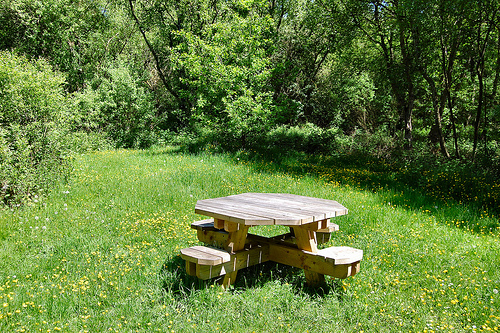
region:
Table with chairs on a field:
[164, 174, 374, 301]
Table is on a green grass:
[19, 124, 497, 331]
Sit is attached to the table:
[297, 237, 376, 291]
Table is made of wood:
[189, 176, 353, 231]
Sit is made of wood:
[174, 239, 237, 290]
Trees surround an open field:
[5, 2, 484, 159]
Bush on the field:
[5, 42, 88, 211]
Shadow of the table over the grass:
[240, 259, 296, 305]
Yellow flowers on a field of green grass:
[8, 254, 116, 314]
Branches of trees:
[356, 19, 493, 136]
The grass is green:
[20, 4, 490, 330]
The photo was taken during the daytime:
[53, 15, 492, 330]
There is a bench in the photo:
[20, 8, 437, 320]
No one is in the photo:
[24, 19, 440, 329]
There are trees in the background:
[25, 17, 483, 289]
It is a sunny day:
[40, 17, 470, 322]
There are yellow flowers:
[23, 41, 455, 329]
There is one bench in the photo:
[21, 6, 478, 326]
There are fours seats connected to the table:
[18, 24, 469, 331]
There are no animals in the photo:
[11, 19, 498, 329]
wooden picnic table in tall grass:
[177, 186, 363, 288]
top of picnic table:
[189, 189, 352, 224]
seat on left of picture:
[310, 243, 366, 277]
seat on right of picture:
[173, 243, 237, 281]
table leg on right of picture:
[286, 227, 326, 293]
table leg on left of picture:
[226, 223, 249, 293]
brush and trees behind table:
[8, 4, 493, 148]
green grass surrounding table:
[24, 153, 488, 329]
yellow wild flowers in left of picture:
[3, 198, 178, 323]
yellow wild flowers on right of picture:
[371, 169, 498, 323]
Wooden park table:
[161, 156, 373, 297]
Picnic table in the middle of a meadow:
[168, 176, 371, 306]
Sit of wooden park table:
[297, 240, 364, 297]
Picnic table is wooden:
[168, 173, 371, 299]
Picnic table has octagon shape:
[186, 170, 351, 235]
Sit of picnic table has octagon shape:
[167, 237, 232, 279]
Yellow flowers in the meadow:
[0, 260, 107, 310]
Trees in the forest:
[0, 5, 495, 150]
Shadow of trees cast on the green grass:
[165, 121, 380, 177]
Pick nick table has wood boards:
[190, 177, 356, 236]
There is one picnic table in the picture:
[105, 82, 395, 327]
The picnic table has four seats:
[47, 20, 432, 325]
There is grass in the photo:
[33, 24, 445, 326]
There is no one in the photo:
[53, 42, 454, 329]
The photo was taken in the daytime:
[40, 37, 430, 294]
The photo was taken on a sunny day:
[33, 18, 477, 331]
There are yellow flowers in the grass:
[16, 2, 456, 318]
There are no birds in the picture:
[18, 11, 373, 298]